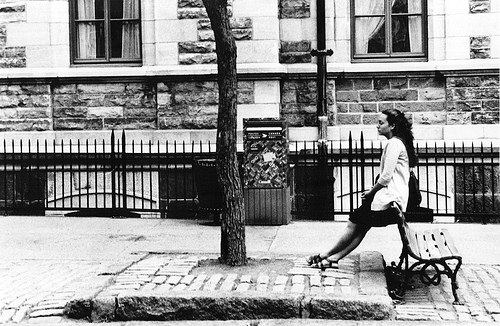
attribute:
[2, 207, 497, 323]
floor — concrete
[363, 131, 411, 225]
sweater — white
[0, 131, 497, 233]
fence — metal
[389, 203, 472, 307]
bench — wooden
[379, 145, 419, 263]
shirt — white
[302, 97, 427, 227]
shirt — white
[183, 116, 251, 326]
tree — tall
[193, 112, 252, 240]
tree — tall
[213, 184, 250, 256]
tree — tall